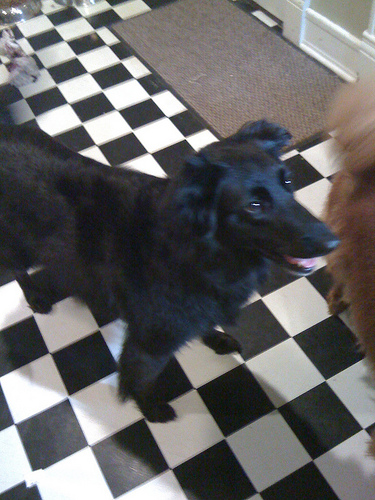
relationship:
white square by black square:
[229, 412, 322, 489] [196, 355, 279, 434]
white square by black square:
[265, 277, 332, 340] [290, 310, 367, 382]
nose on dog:
[298, 223, 343, 264] [1, 115, 344, 404]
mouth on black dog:
[275, 248, 333, 278] [0, 121, 338, 423]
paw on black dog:
[113, 385, 196, 428] [0, 121, 338, 423]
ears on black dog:
[232, 114, 292, 152] [0, 121, 338, 423]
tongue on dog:
[286, 251, 352, 275] [64, 127, 299, 323]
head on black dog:
[177, 125, 336, 277] [0, 121, 338, 423]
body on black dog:
[3, 122, 245, 344] [0, 121, 338, 423]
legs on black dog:
[123, 286, 238, 425] [0, 121, 338, 423]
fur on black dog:
[81, 189, 137, 259] [0, 121, 338, 423]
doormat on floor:
[111, 2, 371, 161] [99, 0, 360, 162]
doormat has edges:
[111, 2, 371, 161] [110, 26, 181, 106]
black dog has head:
[0, 121, 338, 423] [160, 119, 343, 276]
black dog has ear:
[0, 121, 338, 423] [173, 157, 229, 239]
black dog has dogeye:
[0, 121, 338, 423] [245, 196, 264, 211]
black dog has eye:
[0, 121, 338, 423] [281, 177, 291, 188]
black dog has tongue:
[0, 121, 338, 423] [278, 249, 318, 271]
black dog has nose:
[0, 121, 338, 423] [318, 234, 338, 251]